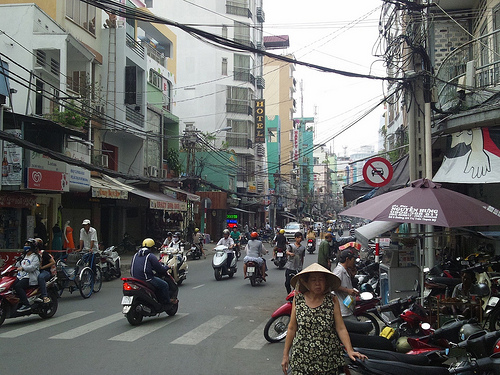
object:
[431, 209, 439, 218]
letters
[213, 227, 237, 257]
person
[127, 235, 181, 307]
man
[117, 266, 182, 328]
motorcycle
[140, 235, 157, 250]
helmet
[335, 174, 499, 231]
umbrella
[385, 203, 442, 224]
white text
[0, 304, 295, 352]
cross walk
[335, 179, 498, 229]
purple umbrella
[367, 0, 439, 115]
tangle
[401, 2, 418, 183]
pole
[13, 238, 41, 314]
person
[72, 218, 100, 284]
mannequin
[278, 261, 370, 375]
people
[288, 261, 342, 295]
hat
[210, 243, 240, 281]
motorcycles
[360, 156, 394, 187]
round sign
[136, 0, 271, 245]
building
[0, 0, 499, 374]
city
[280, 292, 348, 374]
dress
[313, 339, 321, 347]
flowers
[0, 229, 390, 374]
street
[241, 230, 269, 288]
person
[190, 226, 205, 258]
person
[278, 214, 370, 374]
large group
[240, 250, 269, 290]
motorcycle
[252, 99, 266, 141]
hotel